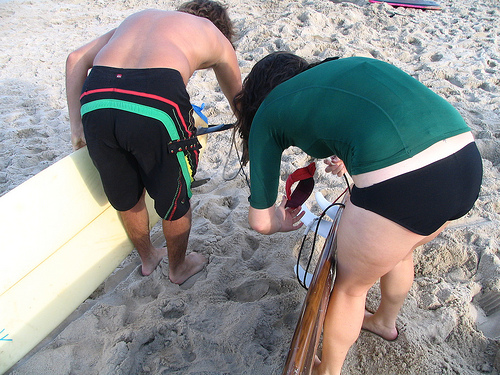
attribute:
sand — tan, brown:
[80, 284, 287, 369]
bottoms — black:
[338, 135, 489, 239]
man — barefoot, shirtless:
[54, 2, 249, 289]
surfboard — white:
[1, 142, 128, 373]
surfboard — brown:
[288, 184, 355, 373]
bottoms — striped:
[80, 59, 206, 223]